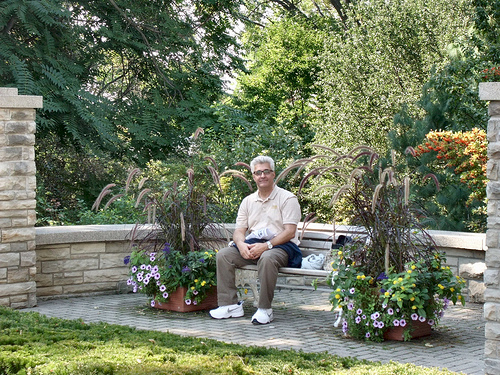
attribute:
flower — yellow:
[445, 298, 455, 309]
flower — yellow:
[435, 281, 445, 291]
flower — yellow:
[407, 263, 418, 270]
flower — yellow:
[357, 274, 363, 281]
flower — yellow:
[333, 290, 341, 302]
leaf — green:
[394, 297, 399, 304]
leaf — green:
[457, 280, 461, 283]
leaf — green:
[433, 270, 438, 275]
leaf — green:
[368, 304, 376, 310]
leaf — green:
[341, 281, 348, 288]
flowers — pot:
[321, 262, 476, 338]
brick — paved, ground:
[381, 322, 466, 371]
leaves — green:
[345, 246, 467, 337]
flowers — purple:
[120, 246, 180, 326]